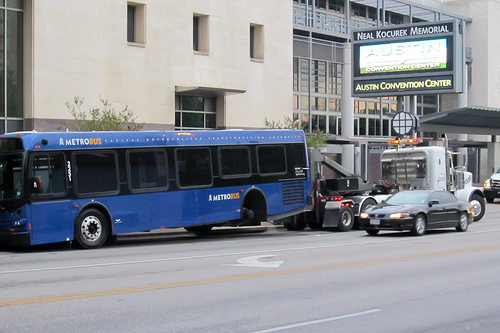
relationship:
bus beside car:
[4, 124, 319, 254] [359, 183, 472, 239]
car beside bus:
[359, 183, 472, 239] [4, 124, 319, 254]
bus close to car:
[4, 124, 319, 254] [359, 183, 472, 239]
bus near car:
[4, 124, 319, 254] [359, 183, 472, 239]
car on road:
[359, 183, 472, 239] [5, 191, 494, 332]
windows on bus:
[67, 146, 280, 196] [4, 124, 319, 254]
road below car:
[5, 191, 494, 332] [359, 183, 472, 239]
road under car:
[5, 191, 494, 332] [359, 183, 472, 239]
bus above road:
[4, 124, 319, 254] [5, 191, 494, 332]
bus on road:
[4, 124, 319, 254] [5, 191, 494, 332]